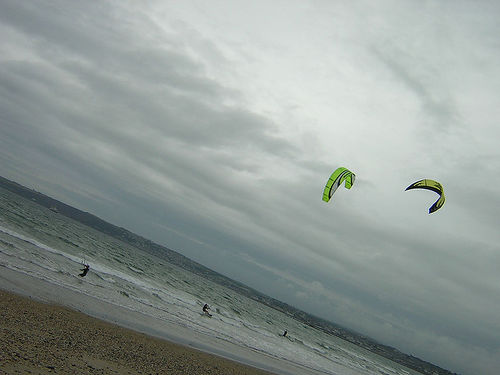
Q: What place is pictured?
A: It is an ocean.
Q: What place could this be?
A: It is an ocean.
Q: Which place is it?
A: It is an ocean.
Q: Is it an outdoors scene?
A: Yes, it is outdoors.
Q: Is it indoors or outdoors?
A: It is outdoors.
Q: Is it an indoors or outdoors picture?
A: It is outdoors.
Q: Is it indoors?
A: No, it is outdoors.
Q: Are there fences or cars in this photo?
A: No, there are no cars or fences.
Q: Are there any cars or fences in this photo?
A: No, there are no cars or fences.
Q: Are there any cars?
A: No, there are no cars.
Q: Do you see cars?
A: No, there are no cars.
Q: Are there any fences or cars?
A: No, there are no cars or fences.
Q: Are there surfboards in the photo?
A: No, there are no surfboards.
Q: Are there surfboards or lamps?
A: No, there are no surfboards or lamps.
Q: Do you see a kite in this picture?
A: Yes, there is a kite.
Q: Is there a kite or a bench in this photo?
A: Yes, there is a kite.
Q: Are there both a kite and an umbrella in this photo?
A: No, there is a kite but no umbrellas.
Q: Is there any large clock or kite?
A: Yes, there is a large kite.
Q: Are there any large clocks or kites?
A: Yes, there is a large kite.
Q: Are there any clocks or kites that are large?
A: Yes, the kite is large.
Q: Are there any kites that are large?
A: Yes, there is a large kite.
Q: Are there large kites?
A: Yes, there is a large kite.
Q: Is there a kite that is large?
A: Yes, there is a kite that is large.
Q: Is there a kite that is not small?
A: Yes, there is a large kite.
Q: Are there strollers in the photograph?
A: No, there are no strollers.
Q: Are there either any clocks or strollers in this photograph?
A: No, there are no strollers or clocks.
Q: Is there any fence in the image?
A: No, there are no fences.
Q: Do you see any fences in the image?
A: No, there are no fences.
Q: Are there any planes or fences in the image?
A: No, there are no fences or planes.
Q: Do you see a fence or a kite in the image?
A: Yes, there is a kite.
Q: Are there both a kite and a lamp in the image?
A: No, there is a kite but no lamps.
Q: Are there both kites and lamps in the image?
A: No, there is a kite but no lamps.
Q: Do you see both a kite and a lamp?
A: No, there is a kite but no lamps.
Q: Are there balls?
A: No, there are no balls.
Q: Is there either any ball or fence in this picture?
A: No, there are no balls or fences.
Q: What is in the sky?
A: The kite is in the sky.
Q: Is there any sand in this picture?
A: Yes, there is sand.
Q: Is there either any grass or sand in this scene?
A: Yes, there is sand.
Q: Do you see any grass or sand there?
A: Yes, there is sand.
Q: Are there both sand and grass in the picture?
A: No, there is sand but no grass.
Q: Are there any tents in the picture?
A: No, there are no tents.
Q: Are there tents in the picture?
A: No, there are no tents.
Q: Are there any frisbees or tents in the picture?
A: No, there are no tents or frisbees.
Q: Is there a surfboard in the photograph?
A: No, there are no surfboards.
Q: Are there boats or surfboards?
A: No, there are no surfboards or boats.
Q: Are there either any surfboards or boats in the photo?
A: No, there are no surfboards or boats.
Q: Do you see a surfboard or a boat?
A: No, there are no surfboards or boats.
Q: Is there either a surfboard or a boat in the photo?
A: No, there are no surfboards or boats.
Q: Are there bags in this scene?
A: No, there are no bags.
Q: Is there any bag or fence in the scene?
A: No, there are no bags or fences.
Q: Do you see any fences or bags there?
A: No, there are no bags or fences.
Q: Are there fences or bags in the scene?
A: No, there are no bags or fences.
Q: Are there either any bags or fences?
A: No, there are no bags or fences.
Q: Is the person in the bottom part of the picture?
A: Yes, the person is in the bottom of the image.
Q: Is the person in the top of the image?
A: No, the person is in the bottom of the image.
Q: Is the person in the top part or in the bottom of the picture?
A: The person is in the bottom of the image.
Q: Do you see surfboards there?
A: No, there are no surfboards.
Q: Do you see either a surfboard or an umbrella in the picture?
A: No, there are no surfboards or umbrellas.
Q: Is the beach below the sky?
A: Yes, the beach is below the sky.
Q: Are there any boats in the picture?
A: No, there are no boats.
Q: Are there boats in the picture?
A: No, there are no boats.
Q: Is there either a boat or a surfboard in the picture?
A: No, there are no boats or surfboards.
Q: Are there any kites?
A: Yes, there is a kite.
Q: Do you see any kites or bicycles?
A: Yes, there is a kite.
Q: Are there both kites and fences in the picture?
A: No, there is a kite but no fences.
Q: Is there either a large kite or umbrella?
A: Yes, there is a large kite.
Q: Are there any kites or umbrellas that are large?
A: Yes, the kite is large.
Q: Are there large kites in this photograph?
A: Yes, there is a large kite.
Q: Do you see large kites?
A: Yes, there is a large kite.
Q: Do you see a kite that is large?
A: Yes, there is a kite that is large.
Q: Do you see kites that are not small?
A: Yes, there is a large kite.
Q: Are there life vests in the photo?
A: No, there are no life vests.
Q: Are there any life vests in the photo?
A: No, there are no life vests.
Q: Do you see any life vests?
A: No, there are no life vests.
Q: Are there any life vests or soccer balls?
A: No, there are no life vests or soccer balls.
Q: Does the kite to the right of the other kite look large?
A: Yes, the kite is large.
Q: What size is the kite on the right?
A: The kite is large.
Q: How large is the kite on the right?
A: The kite is large.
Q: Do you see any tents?
A: No, there are no tents.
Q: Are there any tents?
A: No, there are no tents.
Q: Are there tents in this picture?
A: No, there are no tents.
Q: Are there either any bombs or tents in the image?
A: No, there are no tents or bombs.